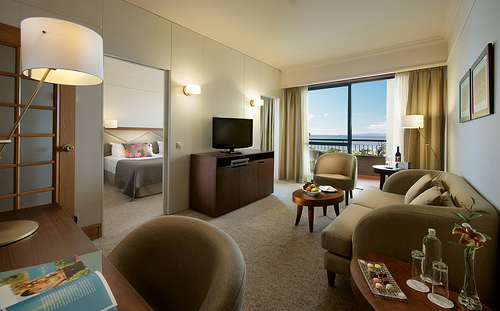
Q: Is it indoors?
A: Yes, it is indoors.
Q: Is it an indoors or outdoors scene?
A: It is indoors.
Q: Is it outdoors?
A: No, it is indoors.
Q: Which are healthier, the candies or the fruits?
A: The fruits are healthier than the candies.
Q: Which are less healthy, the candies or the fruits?
A: The candies are less healthy than the fruits.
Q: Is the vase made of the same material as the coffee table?
A: No, the vase is made of glass and the coffee table is made of wood.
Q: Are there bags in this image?
A: No, there are no bags.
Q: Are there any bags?
A: No, there are no bags.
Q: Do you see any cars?
A: No, there are no cars.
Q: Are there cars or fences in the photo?
A: No, there are no cars or fences.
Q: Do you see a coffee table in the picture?
A: Yes, there is a coffee table.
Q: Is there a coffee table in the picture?
A: Yes, there is a coffee table.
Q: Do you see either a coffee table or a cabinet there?
A: Yes, there is a coffee table.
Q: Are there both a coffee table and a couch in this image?
A: Yes, there are both a coffee table and a couch.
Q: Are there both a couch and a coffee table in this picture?
A: Yes, there are both a coffee table and a couch.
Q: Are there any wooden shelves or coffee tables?
A: Yes, there is a wood coffee table.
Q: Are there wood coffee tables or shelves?
A: Yes, there is a wood coffee table.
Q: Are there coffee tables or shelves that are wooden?
A: Yes, the coffee table is wooden.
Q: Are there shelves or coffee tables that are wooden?
A: Yes, the coffee table is wooden.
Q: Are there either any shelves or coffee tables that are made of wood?
A: Yes, the coffee table is made of wood.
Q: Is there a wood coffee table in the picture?
A: Yes, there is a wood coffee table.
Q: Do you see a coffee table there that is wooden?
A: Yes, there is a coffee table that is wooden.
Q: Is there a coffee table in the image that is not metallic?
A: Yes, there is a wooden coffee table.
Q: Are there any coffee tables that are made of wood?
A: Yes, there is a coffee table that is made of wood.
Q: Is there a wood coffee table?
A: Yes, there is a coffee table that is made of wood.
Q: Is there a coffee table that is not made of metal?
A: Yes, there is a coffee table that is made of wood.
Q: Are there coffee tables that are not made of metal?
A: Yes, there is a coffee table that is made of wood.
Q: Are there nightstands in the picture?
A: No, there are no nightstands.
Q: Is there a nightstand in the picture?
A: No, there are no nightstands.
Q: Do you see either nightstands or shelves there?
A: No, there are no nightstands or shelves.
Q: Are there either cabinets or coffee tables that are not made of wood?
A: No, there is a coffee table but it is made of wood.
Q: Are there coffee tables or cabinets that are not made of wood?
A: No, there is a coffee table but it is made of wood.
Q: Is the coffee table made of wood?
A: Yes, the coffee table is made of wood.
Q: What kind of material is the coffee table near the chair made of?
A: The coffee table is made of wood.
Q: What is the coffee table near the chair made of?
A: The coffee table is made of wood.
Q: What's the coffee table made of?
A: The coffee table is made of wood.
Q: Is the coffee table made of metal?
A: No, the coffee table is made of wood.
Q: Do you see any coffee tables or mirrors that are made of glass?
A: No, there is a coffee table but it is made of wood.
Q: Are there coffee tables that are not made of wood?
A: No, there is a coffee table but it is made of wood.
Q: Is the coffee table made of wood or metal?
A: The coffee table is made of wood.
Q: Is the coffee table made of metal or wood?
A: The coffee table is made of wood.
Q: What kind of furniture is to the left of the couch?
A: The piece of furniture is a coffee table.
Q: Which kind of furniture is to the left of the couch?
A: The piece of furniture is a coffee table.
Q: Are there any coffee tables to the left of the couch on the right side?
A: Yes, there is a coffee table to the left of the couch.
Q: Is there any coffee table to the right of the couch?
A: No, the coffee table is to the left of the couch.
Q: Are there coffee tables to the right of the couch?
A: No, the coffee table is to the left of the couch.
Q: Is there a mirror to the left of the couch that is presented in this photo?
A: No, there is a coffee table to the left of the couch.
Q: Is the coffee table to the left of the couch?
A: Yes, the coffee table is to the left of the couch.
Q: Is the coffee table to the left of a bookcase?
A: No, the coffee table is to the left of the couch.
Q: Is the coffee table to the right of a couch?
A: No, the coffee table is to the left of a couch.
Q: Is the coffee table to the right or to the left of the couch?
A: The coffee table is to the left of the couch.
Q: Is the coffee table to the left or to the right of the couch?
A: The coffee table is to the left of the couch.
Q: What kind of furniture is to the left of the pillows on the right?
A: The piece of furniture is a coffee table.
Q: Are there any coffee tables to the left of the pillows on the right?
A: Yes, there is a coffee table to the left of the pillows.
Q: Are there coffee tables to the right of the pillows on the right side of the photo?
A: No, the coffee table is to the left of the pillows.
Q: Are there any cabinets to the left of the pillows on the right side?
A: No, there is a coffee table to the left of the pillows.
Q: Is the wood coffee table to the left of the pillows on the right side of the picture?
A: Yes, the coffee table is to the left of the pillows.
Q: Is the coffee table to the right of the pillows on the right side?
A: No, the coffee table is to the left of the pillows.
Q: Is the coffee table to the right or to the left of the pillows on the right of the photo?
A: The coffee table is to the left of the pillows.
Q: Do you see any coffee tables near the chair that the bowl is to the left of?
A: Yes, there is a coffee table near the chair.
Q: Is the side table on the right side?
A: Yes, the side table is on the right of the image.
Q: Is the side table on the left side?
A: No, the side table is on the right of the image.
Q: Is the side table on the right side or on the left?
A: The side table is on the right of the image.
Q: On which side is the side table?
A: The side table is on the right of the image.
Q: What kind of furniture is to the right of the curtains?
A: The piece of furniture is a side table.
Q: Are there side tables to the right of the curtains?
A: Yes, there is a side table to the right of the curtains.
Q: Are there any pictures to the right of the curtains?
A: No, there is a side table to the right of the curtains.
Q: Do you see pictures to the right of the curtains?
A: No, there is a side table to the right of the curtains.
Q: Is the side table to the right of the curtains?
A: Yes, the side table is to the right of the curtains.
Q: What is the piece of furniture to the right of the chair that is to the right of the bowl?
A: The piece of furniture is a side table.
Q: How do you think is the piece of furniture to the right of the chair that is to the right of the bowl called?
A: The piece of furniture is a side table.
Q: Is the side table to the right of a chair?
A: Yes, the side table is to the right of a chair.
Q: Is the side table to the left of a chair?
A: No, the side table is to the right of a chair.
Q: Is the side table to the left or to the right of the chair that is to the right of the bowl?
A: The side table is to the right of the chair.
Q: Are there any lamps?
A: Yes, there is a lamp.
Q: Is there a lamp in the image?
A: Yes, there is a lamp.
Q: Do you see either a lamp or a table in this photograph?
A: Yes, there is a lamp.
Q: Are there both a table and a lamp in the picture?
A: Yes, there are both a lamp and a table.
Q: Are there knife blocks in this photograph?
A: No, there are no knife blocks.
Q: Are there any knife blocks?
A: No, there are no knife blocks.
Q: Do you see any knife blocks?
A: No, there are no knife blocks.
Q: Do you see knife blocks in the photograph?
A: No, there are no knife blocks.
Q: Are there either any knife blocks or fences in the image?
A: No, there are no knife blocks or fences.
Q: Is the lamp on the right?
A: Yes, the lamp is on the right of the image.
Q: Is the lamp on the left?
A: No, the lamp is on the right of the image.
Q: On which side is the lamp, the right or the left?
A: The lamp is on the right of the image.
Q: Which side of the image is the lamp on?
A: The lamp is on the right of the image.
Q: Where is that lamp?
A: The lamp is on the floor.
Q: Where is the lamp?
A: The lamp is on the floor.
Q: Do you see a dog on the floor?
A: No, there is a lamp on the floor.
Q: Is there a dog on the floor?
A: No, there is a lamp on the floor.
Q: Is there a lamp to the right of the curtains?
A: Yes, there is a lamp to the right of the curtains.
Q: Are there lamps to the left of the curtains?
A: No, the lamp is to the right of the curtains.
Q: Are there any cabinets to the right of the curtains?
A: No, there is a lamp to the right of the curtains.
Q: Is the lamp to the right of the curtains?
A: Yes, the lamp is to the right of the curtains.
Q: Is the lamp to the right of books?
A: No, the lamp is to the right of the curtains.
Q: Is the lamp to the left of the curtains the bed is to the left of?
A: No, the lamp is to the right of the curtains.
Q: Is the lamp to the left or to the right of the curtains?
A: The lamp is to the right of the curtains.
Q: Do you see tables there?
A: Yes, there is a table.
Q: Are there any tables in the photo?
A: Yes, there is a table.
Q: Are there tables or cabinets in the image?
A: Yes, there is a table.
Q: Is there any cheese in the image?
A: No, there is no cheese.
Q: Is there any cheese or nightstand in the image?
A: No, there are no cheese or nightstands.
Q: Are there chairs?
A: Yes, there is a chair.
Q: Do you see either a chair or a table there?
A: Yes, there is a chair.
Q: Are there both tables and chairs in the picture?
A: Yes, there are both a chair and a table.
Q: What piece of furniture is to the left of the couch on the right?
A: The piece of furniture is a chair.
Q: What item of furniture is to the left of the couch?
A: The piece of furniture is a chair.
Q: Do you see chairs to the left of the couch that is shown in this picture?
A: Yes, there is a chair to the left of the couch.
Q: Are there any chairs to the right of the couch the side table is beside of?
A: No, the chair is to the left of the couch.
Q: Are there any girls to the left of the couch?
A: No, there is a chair to the left of the couch.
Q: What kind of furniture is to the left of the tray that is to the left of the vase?
A: The piece of furniture is a chair.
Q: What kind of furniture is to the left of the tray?
A: The piece of furniture is a chair.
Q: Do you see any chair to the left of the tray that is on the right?
A: Yes, there is a chair to the left of the tray.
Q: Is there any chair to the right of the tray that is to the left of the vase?
A: No, the chair is to the left of the tray.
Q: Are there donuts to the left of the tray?
A: No, there is a chair to the left of the tray.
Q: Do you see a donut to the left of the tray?
A: No, there is a chair to the left of the tray.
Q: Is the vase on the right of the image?
A: Yes, the vase is on the right of the image.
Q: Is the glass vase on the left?
A: No, the vase is on the right of the image.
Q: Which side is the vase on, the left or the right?
A: The vase is on the right of the image.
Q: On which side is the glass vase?
A: The vase is on the right of the image.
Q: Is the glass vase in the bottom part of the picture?
A: Yes, the vase is in the bottom of the image.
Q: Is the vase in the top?
A: No, the vase is in the bottom of the image.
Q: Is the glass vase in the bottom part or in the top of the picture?
A: The vase is in the bottom of the image.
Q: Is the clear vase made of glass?
A: Yes, the vase is made of glass.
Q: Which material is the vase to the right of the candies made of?
A: The vase is made of glass.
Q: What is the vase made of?
A: The vase is made of glass.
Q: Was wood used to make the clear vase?
A: No, the vase is made of glass.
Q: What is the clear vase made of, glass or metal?
A: The vase is made of glass.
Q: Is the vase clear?
A: Yes, the vase is clear.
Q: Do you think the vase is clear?
A: Yes, the vase is clear.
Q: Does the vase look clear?
A: Yes, the vase is clear.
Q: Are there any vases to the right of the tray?
A: Yes, there is a vase to the right of the tray.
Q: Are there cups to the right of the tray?
A: No, there is a vase to the right of the tray.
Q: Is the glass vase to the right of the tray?
A: Yes, the vase is to the right of the tray.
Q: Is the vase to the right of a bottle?
A: No, the vase is to the right of the tray.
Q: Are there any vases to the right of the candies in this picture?
A: Yes, there is a vase to the right of the candies.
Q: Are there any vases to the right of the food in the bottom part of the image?
A: Yes, there is a vase to the right of the candies.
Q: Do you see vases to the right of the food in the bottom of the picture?
A: Yes, there is a vase to the right of the candies.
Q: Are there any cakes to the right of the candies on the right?
A: No, there is a vase to the right of the candies.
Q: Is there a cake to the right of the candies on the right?
A: No, there is a vase to the right of the candies.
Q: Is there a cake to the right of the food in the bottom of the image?
A: No, there is a vase to the right of the candies.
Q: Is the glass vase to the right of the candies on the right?
A: Yes, the vase is to the right of the candies.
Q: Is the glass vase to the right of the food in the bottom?
A: Yes, the vase is to the right of the candies.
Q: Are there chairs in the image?
A: Yes, there is a chair.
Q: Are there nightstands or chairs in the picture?
A: Yes, there is a chair.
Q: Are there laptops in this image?
A: No, there are no laptops.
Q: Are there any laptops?
A: No, there are no laptops.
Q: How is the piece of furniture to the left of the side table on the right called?
A: The piece of furniture is a chair.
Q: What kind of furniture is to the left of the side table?
A: The piece of furniture is a chair.